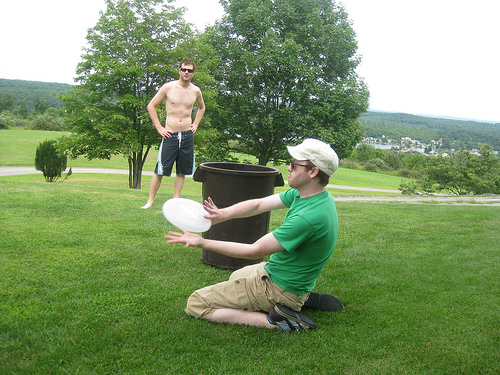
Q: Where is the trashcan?
A: Sitting in the grass.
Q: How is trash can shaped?
A: Round.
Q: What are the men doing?
A: Throwing frisbee.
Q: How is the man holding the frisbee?
A: In both hand.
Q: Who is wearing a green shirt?
A: Man on ground.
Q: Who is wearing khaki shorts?
A: Man on ground.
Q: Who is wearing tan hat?
A: Man on ground.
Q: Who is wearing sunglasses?
A: Both men.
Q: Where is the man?
A: Sitting in grass.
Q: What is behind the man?
A: Two trees.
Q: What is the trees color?
A: Green.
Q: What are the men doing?
A: Playing frisbee.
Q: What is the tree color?
A: Green.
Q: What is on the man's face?
A: Glasses.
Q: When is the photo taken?
A: Day time.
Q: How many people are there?
A: Two.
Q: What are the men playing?
A: Frisbee.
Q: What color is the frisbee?
A: White.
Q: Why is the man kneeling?
A: To catch the frisbee.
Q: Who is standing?
A: A man.